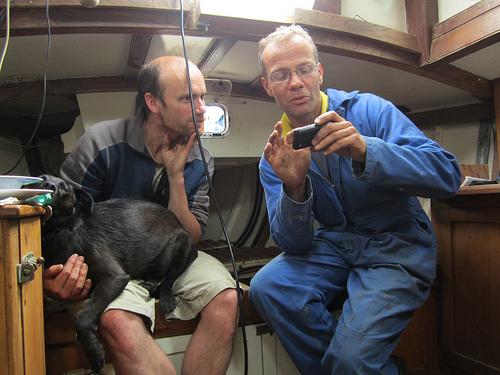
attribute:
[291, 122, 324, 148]
cellphone — small, black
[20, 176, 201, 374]
lab — black, sleeping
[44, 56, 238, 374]
man — bald, sitting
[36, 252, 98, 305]
hand — curled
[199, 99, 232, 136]
window — small, open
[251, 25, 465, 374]
man — sitting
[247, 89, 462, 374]
overalls — blue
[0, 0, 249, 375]
wires — electric, hanging down, black, hanging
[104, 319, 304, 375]
cabinets — white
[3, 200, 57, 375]
cabinet — wood, brown, wooden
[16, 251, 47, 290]
lock — tarnished, metal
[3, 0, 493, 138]
frame — wooden, curved, brown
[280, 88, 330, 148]
collar — yellow, undershit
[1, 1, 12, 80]
cord — white, short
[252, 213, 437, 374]
trouser — dirty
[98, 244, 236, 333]
shorts — khaki